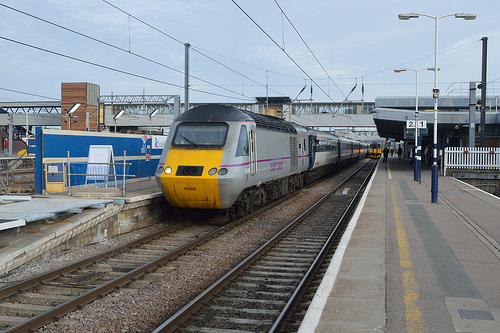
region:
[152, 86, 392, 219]
two trains on the train tracks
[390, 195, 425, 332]
faded yellow line painted on the ground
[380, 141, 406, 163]
people standing near the train tracks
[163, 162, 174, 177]
headlight on the front of the train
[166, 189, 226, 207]
dark marks on the yellow paint of the train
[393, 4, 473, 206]
light post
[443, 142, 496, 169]
white picket fence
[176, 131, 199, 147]
skinny black windshield wiper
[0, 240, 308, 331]
two parallel train tracks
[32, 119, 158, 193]
blue wall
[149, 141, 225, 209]
a yellow section on a train.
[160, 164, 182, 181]
a head light on a train.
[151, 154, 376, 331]
a set of rusted train tracks.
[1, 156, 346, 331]
a set of brown train tracks.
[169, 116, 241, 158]
a windshield on a train.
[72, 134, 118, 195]
a marker board near tracks.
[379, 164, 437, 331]
a yellow line on a loading platform.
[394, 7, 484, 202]
a street light near a loading platform.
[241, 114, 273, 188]
a door on a train.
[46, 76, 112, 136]
a brown box on a building.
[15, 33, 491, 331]
A train station scene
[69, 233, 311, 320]
Two sets of train tracks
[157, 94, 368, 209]
A train is at the station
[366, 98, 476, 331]
This is the platform area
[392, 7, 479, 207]
Lamp posts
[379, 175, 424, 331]
A yellow line is painted on the platform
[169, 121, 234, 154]
The train's wind screen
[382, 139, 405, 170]
People are waiting on the platform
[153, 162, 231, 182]
The train's headlights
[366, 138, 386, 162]
Another train is in the background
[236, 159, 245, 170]
THE LINE IS PINK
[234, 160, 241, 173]
THE LINE IS PINK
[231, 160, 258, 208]
THE LINE IS PINK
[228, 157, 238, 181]
THE LINE IS PINK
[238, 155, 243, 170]
THE LINE IS PINK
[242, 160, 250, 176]
THE LINE IS PINK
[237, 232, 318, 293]
brown tracks for train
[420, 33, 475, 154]
gray train stop lights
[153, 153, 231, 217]
yellow front of train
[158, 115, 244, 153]
front window of train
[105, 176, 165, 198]
paved surface of train stop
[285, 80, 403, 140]
area lobby in back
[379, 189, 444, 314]
yellow painting on stop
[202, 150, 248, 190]
headlights of the train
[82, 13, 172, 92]
electric cables over train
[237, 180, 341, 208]
wheels of the train